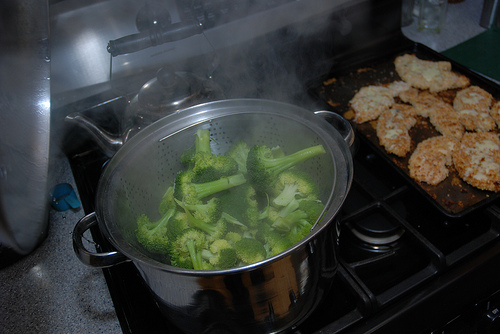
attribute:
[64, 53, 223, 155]
kettle — silver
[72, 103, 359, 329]
cooking pot — nice, shiny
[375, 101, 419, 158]
meat — breaded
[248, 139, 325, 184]
broccoli — green, piece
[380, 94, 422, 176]
chicken nugget — piece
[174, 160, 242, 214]
broccoli — green, piece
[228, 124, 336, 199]
broccoli — green, piece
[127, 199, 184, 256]
broccoli — green, piece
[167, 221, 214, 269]
broccoli — green, piece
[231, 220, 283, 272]
broccoli — green, piece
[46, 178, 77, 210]
cup — blue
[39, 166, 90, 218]
blue cup — measuring cup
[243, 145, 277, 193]
leaf — broccoli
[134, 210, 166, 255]
leaf — broccoli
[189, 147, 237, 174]
leaf — broccoli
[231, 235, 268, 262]
leaf — broccoli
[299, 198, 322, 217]
leaf — broccoli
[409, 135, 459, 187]
meat — breaded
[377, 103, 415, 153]
meat — breaded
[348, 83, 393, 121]
meat — breaded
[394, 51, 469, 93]
meat — breaded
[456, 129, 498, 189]
meat — breaded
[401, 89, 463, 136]
meat — breaded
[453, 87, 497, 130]
meat — breaded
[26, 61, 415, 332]
pot — cooking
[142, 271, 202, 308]
pot — shiny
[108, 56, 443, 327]
stove — black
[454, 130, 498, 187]
nugget — chicken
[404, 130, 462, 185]
nugget — chicken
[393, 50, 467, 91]
nugget — chicken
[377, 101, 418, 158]
nugget — chicken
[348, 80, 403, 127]
nugget — chicken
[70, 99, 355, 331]
pot — cooking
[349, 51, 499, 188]
chicken — fried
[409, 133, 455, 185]
chicken — piece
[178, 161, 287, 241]
broccoli spears — green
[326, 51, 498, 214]
food — part, being cooked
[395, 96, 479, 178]
food — part, being cooked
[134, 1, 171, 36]
button — black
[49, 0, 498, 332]
stove — on, cook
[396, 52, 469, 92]
food — being cooked, part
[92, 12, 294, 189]
smoke — white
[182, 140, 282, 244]
broccoli — cooked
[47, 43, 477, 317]
stove — cooking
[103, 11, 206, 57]
handle — black